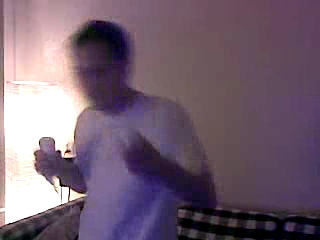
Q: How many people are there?
A: One.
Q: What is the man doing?
A: Standing.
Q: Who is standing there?
A: A man.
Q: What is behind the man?
A: A couch.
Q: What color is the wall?
A: White.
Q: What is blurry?
A: The man's face.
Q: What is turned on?
A: The light.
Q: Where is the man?
A: In a living room.